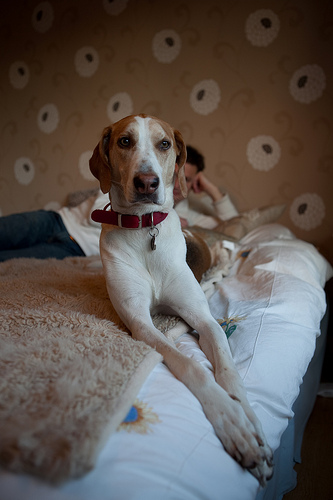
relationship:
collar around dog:
[91, 209, 168, 229] [89, 112, 277, 487]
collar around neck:
[91, 209, 168, 229] [101, 198, 177, 230]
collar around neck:
[89, 203, 188, 229] [94, 191, 191, 230]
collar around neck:
[91, 209, 168, 229] [104, 204, 177, 227]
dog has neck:
[89, 112, 277, 487] [104, 204, 177, 227]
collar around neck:
[91, 209, 168, 229] [105, 195, 178, 239]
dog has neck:
[89, 112, 277, 487] [105, 195, 178, 239]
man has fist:
[0, 142, 241, 262] [190, 170, 206, 192]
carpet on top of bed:
[288, 362, 330, 498] [11, 222, 328, 495]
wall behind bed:
[0, 0, 332, 246] [11, 222, 328, 495]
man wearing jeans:
[0, 142, 241, 262] [9, 201, 81, 270]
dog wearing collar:
[89, 112, 277, 487] [87, 202, 181, 236]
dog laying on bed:
[89, 112, 277, 487] [11, 222, 328, 495]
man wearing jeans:
[0, 142, 241, 262] [0, 209, 87, 276]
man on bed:
[0, 142, 243, 261] [11, 222, 328, 495]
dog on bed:
[89, 112, 277, 487] [11, 222, 328, 495]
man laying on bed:
[0, 142, 243, 261] [11, 222, 328, 495]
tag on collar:
[149, 229, 157, 254] [89, 210, 169, 231]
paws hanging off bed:
[197, 391, 285, 480] [2, 205, 316, 488]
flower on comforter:
[112, 391, 158, 439] [4, 220, 327, 464]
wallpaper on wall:
[186, 15, 320, 187] [0, 2, 321, 227]